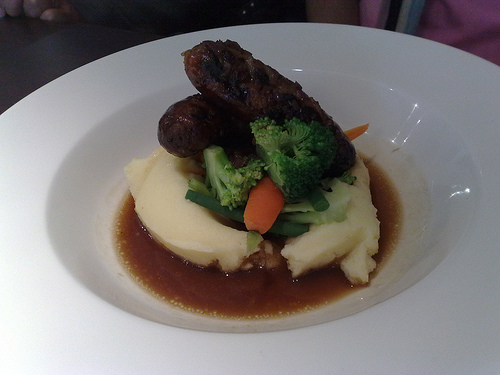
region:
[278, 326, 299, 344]
the plate is white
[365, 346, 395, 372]
the plate is white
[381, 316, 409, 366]
the plate is white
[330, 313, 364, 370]
the plate is white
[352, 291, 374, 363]
the plate is white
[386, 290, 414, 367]
the plate is white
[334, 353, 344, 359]
the plate is white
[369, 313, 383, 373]
the plate is white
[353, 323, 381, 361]
the plate is white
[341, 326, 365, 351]
the plate is white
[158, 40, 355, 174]
two pieces of sausage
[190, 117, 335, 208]
pieces of steamed brocolli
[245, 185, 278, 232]
orange steamed carrot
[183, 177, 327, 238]
green beans under a carrot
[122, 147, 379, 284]
mashed white potatoes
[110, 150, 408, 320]
brown gravy in a bowl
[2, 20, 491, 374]
white china bowl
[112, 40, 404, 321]
sausage with vegetables and gravy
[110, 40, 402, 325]
meat and potatoes entree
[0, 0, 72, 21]
knuckles on a table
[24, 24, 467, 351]
white bowl with food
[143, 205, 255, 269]
mashed potatoes in gravy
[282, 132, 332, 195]
floret on top of broccoli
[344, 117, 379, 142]
tip of cooked carrot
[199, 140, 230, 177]
cut stem of broccoli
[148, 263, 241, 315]
brown gravy in bowl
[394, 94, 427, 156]
light reflection on bowl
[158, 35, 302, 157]
two cook sausages behind broccoli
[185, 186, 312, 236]
green bean on mashed potato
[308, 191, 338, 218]
end of cut green bean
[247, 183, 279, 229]
Orange mini carrot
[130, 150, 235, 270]
Mashed potatoes with gravy sauce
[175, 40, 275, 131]
Delicious meat on a plate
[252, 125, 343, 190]
Steamed broccoli on a plate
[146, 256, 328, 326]
Gravy sauce under mashed potatoes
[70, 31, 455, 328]
Main course entree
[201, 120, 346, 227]
Steamed vegetables on top of potatoes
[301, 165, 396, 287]
Mashed potatoes within a meal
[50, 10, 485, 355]
Fine dining, main entree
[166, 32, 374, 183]
Food ready to eat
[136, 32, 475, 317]
delicious meal on a white plate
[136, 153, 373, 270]
potatoes in gravy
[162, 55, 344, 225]
broccoli's on potatoes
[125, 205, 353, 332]
juices from the gravy in the plate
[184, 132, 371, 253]
carrot in the middle of broccoli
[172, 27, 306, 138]
meat on top of the meal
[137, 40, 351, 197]
meat on top of the broccoli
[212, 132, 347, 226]
green broccoli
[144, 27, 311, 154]
dark brown meat on broccoli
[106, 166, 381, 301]
mashed potatoes under broccoli